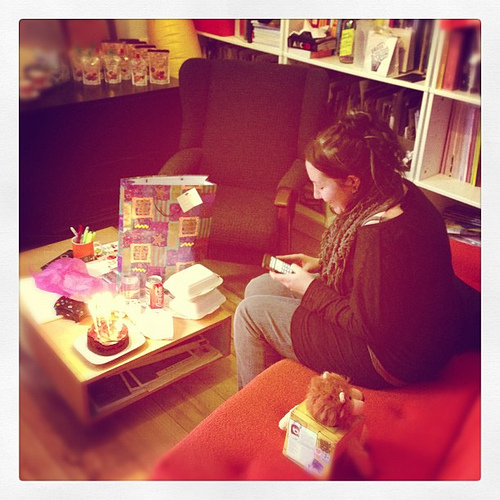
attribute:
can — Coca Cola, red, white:
[141, 273, 166, 311]